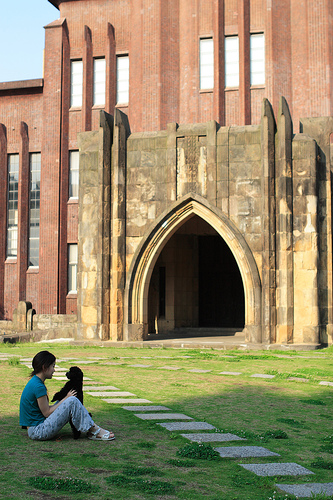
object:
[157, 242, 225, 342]
arch way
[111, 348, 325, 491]
grass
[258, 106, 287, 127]
ground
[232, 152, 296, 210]
stone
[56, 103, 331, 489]
structure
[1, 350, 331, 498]
tiles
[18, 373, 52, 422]
shirt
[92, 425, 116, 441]
sandals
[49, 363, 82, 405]
dog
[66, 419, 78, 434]
legs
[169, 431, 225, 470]
plant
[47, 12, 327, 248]
building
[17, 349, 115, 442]
girl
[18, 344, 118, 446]
girl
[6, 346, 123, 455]
lady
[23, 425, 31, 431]
skin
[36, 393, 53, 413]
skin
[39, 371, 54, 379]
skin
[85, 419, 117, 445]
sandals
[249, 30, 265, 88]
window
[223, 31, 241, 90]
window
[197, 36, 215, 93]
window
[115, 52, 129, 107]
window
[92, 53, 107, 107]
window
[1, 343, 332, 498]
yard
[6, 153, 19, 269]
windows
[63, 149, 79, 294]
windows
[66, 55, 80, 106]
windows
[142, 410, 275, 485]
footstep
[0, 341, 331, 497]
grass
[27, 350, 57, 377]
hair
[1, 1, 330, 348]
wall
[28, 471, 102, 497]
weeds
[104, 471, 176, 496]
weeds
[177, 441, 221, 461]
weeds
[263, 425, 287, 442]
weeds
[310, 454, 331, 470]
weeds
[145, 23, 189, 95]
wall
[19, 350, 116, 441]
woman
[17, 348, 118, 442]
she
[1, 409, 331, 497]
shadow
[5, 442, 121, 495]
grass